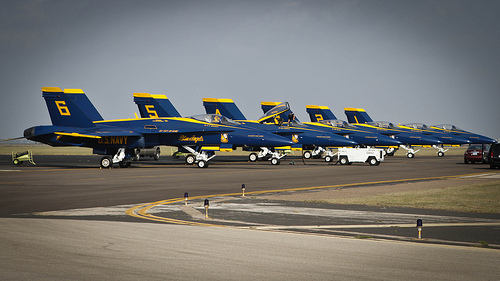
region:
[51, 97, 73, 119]
The jet's number is six.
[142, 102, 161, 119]
The jet's number is five.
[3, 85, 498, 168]
The jets are blue and yellow.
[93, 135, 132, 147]
The jets belong to the U.S. Navy.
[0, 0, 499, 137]
The sky is a hazy light blue.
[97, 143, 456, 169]
The jet's landing gear is down.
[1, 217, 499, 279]
Part of the road is light gray.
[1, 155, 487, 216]
Part of the road is dark gray.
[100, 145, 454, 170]
The landing gear is white.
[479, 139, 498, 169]
The vehicle's door is open.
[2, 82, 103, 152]
the tail of a plane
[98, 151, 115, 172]
a wheel of the plane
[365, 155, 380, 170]
a wheel on the car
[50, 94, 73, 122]
a number on the plane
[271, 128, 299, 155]
the nose of the plane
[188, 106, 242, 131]
a window on the plane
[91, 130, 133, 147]
writing on the plane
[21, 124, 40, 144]
the afterburner of the plane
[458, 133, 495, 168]
a car on the tarmac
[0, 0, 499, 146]
a clear sky overhead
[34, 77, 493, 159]
a row of blue planes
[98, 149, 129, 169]
the landing gear of a plane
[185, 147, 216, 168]
the landing gear of a plane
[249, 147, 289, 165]
the landing gear of a plane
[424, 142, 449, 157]
the landing gear of a plane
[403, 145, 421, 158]
the landing gear of a plane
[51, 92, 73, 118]
a yellow number on a tail of a plane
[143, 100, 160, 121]
a yellow number on a tail of a plane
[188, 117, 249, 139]
the nose of a plane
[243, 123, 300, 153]
the nose of a plane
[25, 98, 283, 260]
These are navy planes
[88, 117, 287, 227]
The planes are dark blue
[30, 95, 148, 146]
The planes have yellow numbers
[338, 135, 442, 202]
This is a truck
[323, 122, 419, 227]
The truck is white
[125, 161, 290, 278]
These are small lights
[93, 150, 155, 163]
These are wheels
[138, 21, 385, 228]
The sky is grey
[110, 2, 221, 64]
The sky is cloudy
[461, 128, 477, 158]
This is a picture of a red vehicle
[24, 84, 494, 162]
A row of US Navy Jets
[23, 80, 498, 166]
Navy jets on the tarmac.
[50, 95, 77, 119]
US Navy Jet with a numeral 6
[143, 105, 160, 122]
US Navy Jet with a number 5 on it.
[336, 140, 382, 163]
Small aircraft servicing vehicle.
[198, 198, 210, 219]
Guide light on the tarmac.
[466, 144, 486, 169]
Small red car on the tarmac.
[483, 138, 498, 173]
SUV with a door ajar.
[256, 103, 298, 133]
US Navy Jet with cockpit open.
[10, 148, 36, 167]
Small item used to service Navy Jets